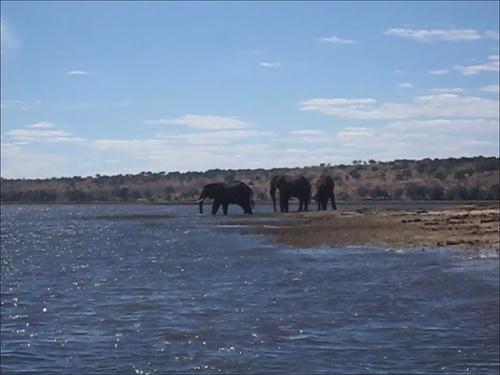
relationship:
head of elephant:
[194, 165, 220, 213] [192, 160, 247, 230]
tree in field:
[405, 178, 426, 204] [0, 153, 499, 203]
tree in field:
[421, 178, 443, 201] [0, 153, 499, 203]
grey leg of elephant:
[281, 189, 293, 209] [268, 173, 312, 212]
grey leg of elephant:
[283, 189, 291, 209] [268, 166, 314, 223]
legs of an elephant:
[205, 200, 258, 215] [194, 180, 255, 217]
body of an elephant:
[210, 179, 256, 202] [194, 180, 255, 217]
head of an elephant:
[268, 170, 282, 190] [261, 169, 310, 217]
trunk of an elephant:
[268, 184, 278, 212] [267, 172, 310, 210]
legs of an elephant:
[277, 200, 311, 212] [266, 168, 312, 217]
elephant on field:
[194, 180, 255, 217] [2, 152, 485, 243]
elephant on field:
[270, 173, 312, 217] [2, 152, 485, 243]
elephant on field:
[313, 172, 338, 211] [2, 152, 485, 243]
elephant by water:
[194, 180, 255, 217] [3, 203, 483, 373]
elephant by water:
[268, 173, 312, 212] [3, 203, 483, 373]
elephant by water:
[304, 166, 339, 217] [3, 203, 483, 373]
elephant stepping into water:
[194, 180, 255, 217] [3, 203, 483, 373]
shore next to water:
[214, 204, 484, 263] [3, 203, 483, 373]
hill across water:
[2, 152, 485, 203] [3, 203, 483, 373]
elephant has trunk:
[268, 173, 312, 212] [266, 191, 280, 216]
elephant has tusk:
[194, 180, 255, 217] [193, 197, 205, 207]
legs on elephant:
[210, 200, 220, 214] [193, 177, 255, 218]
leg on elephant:
[219, 196, 232, 220] [194, 180, 255, 217]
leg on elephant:
[241, 203, 254, 216] [194, 180, 255, 217]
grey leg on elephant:
[283, 189, 291, 209] [264, 174, 315, 221]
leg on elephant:
[310, 197, 323, 212] [310, 165, 341, 218]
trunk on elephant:
[192, 195, 205, 217] [194, 180, 255, 217]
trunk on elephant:
[265, 190, 282, 212] [268, 173, 312, 212]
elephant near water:
[194, 180, 255, 217] [3, 203, 483, 373]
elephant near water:
[268, 173, 312, 212] [3, 203, 483, 373]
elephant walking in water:
[194, 180, 255, 217] [3, 203, 483, 373]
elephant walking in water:
[268, 173, 312, 212] [3, 203, 483, 373]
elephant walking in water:
[313, 172, 338, 211] [3, 203, 483, 373]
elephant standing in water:
[194, 180, 255, 217] [3, 203, 483, 373]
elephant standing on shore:
[268, 173, 312, 212] [248, 204, 499, 263]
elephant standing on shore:
[313, 172, 338, 211] [248, 204, 499, 263]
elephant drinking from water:
[194, 180, 255, 217] [3, 203, 483, 373]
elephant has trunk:
[194, 180, 255, 217] [196, 192, 206, 212]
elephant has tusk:
[194, 180, 255, 217] [192, 193, 207, 206]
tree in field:
[439, 167, 473, 210] [149, 180, 499, 275]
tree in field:
[389, 158, 416, 185] [159, 172, 499, 255]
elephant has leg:
[205, 178, 262, 216] [235, 190, 262, 220]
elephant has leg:
[268, 173, 312, 212] [297, 193, 307, 214]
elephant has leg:
[268, 173, 312, 212] [298, 194, 314, 213]